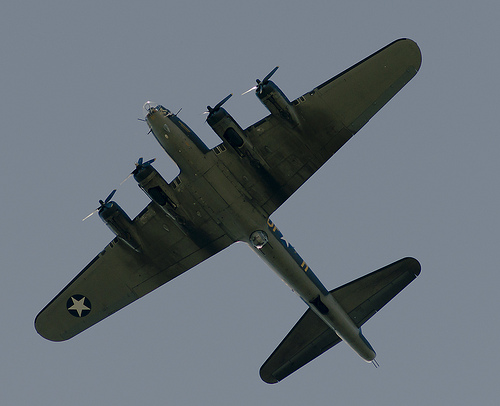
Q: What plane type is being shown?
A: DC-10.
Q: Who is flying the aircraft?
A: The pilot.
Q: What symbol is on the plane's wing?
A: A star.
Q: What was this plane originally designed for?
A: War.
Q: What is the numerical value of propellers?
A: 4.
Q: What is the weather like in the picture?
A: Overcast.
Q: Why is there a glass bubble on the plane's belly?
A: For observation and for a machine gunner.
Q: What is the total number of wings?
A: 4.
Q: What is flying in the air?
A: A plane.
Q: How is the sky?
A: Hazy and blue.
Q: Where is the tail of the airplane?
A: In the back of the plane.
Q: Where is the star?
A: On the wing.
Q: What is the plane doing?
A: Flying.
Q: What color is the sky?
A: Blue.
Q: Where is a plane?
A: In the air.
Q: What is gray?
A: An airplane.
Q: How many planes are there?
A: One.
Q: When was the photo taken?
A: Daytime.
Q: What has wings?
A: A plane.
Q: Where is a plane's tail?
A: On the back.